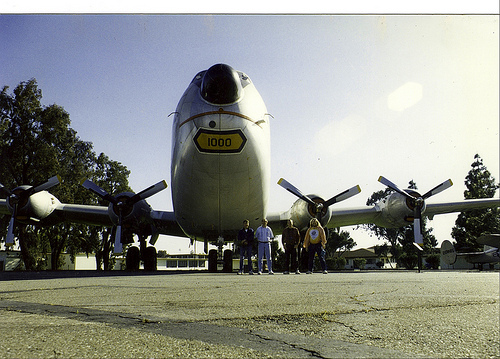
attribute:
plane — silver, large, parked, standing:
[2, 60, 498, 271]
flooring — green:
[2, 269, 497, 357]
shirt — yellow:
[303, 226, 327, 249]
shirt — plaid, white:
[255, 224, 273, 241]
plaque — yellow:
[194, 128, 247, 154]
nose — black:
[199, 64, 244, 102]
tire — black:
[144, 246, 157, 272]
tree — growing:
[5, 78, 99, 277]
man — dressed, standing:
[253, 217, 276, 275]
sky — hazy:
[1, 15, 498, 251]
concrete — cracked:
[0, 272, 496, 359]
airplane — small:
[440, 231, 499, 263]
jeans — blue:
[237, 253, 254, 272]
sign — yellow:
[191, 130, 248, 155]